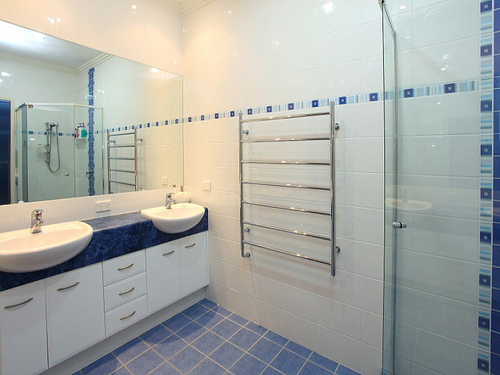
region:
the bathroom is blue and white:
[7, 5, 494, 373]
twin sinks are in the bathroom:
[3, 195, 204, 273]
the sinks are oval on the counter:
[2, 200, 204, 277]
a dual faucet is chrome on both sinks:
[30, 190, 177, 237]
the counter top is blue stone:
[6, 207, 209, 289]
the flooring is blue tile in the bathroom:
[71, 298, 362, 373]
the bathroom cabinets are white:
[6, 235, 218, 372]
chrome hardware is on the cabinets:
[8, 237, 209, 337]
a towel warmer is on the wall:
[229, 98, 348, 278]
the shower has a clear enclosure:
[368, 1, 495, 373]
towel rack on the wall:
[238, 86, 338, 305]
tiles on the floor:
[133, 295, 373, 367]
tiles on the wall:
[204, 71, 496, 370]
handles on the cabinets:
[14, 238, 208, 363]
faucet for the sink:
[160, 191, 184, 213]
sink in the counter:
[2, 211, 99, 279]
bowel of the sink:
[133, 195, 210, 237]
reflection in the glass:
[11, 73, 182, 182]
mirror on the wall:
[7, 64, 201, 215]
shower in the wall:
[3, 95, 110, 211]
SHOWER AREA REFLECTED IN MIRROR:
[10, 89, 112, 205]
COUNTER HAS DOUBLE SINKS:
[7, 183, 216, 283]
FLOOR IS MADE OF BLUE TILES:
[65, 291, 429, 373]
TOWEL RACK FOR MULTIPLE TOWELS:
[220, 98, 355, 283]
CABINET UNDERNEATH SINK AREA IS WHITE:
[2, 248, 244, 365]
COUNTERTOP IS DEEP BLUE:
[2, 198, 212, 294]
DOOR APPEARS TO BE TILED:
[381, 91, 492, 365]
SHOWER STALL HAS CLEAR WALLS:
[13, 94, 115, 205]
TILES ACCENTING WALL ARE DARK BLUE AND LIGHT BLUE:
[188, 73, 477, 138]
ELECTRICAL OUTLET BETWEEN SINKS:
[87, 192, 127, 219]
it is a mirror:
[0, 48, 187, 188]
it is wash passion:
[0, 216, 100, 275]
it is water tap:
[30, 207, 50, 234]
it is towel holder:
[234, 97, 350, 278]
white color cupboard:
[0, 230, 210, 372]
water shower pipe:
[44, 122, 63, 181]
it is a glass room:
[378, 2, 491, 374]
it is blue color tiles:
[142, 330, 279, 373]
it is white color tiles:
[282, 275, 381, 343]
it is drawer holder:
[118, 285, 140, 298]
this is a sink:
[3, 211, 101, 280]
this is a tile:
[186, 322, 226, 374]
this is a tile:
[212, 312, 254, 352]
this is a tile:
[271, 352, 296, 370]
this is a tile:
[119, 340, 156, 365]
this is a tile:
[164, 340, 196, 365]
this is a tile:
[246, 332, 288, 371]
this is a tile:
[126, 349, 163, 371]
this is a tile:
[215, 339, 238, 367]